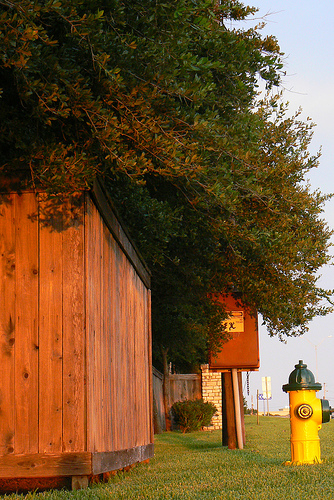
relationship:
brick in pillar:
[206, 392, 209, 395] [205, 366, 217, 400]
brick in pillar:
[214, 375, 218, 380] [205, 366, 217, 400]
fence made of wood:
[93, 226, 117, 434] [45, 385, 61, 410]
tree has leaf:
[17, 7, 255, 202] [269, 216, 281, 221]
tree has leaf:
[17, 7, 255, 202] [50, 95, 64, 100]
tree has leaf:
[17, 7, 255, 202] [172, 6, 195, 16]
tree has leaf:
[17, 7, 255, 202] [188, 58, 199, 68]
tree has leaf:
[17, 7, 255, 202] [161, 226, 167, 231]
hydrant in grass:
[285, 355, 325, 473] [165, 456, 269, 498]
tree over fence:
[17, 7, 255, 202] [93, 226, 117, 434]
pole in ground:
[234, 390, 247, 448] [178, 440, 207, 457]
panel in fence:
[72, 243, 82, 436] [93, 226, 117, 434]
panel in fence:
[24, 210, 35, 470] [93, 226, 117, 434]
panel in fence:
[140, 292, 152, 440] [93, 226, 117, 434]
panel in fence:
[126, 287, 134, 445] [93, 226, 117, 434]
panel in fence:
[5, 218, 10, 476] [93, 226, 117, 434]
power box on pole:
[229, 310, 248, 363] [234, 390, 247, 448]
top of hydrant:
[294, 364, 312, 385] [285, 355, 325, 473]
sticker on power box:
[236, 315, 242, 329] [229, 310, 248, 363]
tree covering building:
[17, 7, 255, 202] [1, 161, 157, 487]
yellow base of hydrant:
[281, 389, 321, 465] [281, 359, 332, 464]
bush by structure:
[169, 398, 211, 433] [198, 357, 231, 433]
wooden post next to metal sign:
[229, 369, 245, 452] [206, 281, 259, 371]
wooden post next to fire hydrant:
[229, 369, 245, 452] [281, 358, 333, 465]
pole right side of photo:
[322, 380, 325, 397] [1, 1, 332, 495]